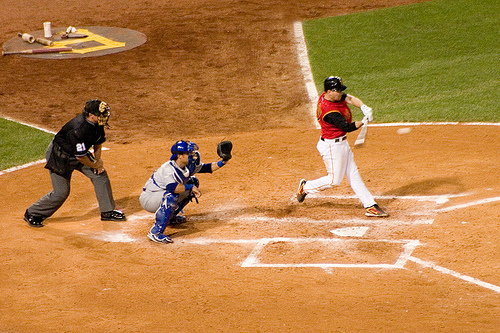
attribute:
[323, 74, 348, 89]
headgear — black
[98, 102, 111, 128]
mask — black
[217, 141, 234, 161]
mitt — black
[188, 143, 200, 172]
mask — blue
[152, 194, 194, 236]
shinguards — blue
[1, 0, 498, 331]
ground — brown, green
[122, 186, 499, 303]
lines — white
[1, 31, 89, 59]
bats — brown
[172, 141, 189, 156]
helmet — blue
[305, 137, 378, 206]
pants — white